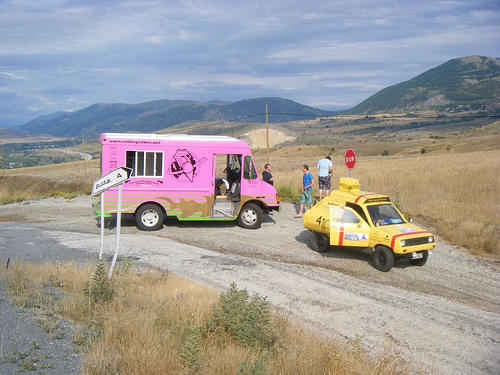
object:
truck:
[99, 132, 280, 231]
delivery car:
[302, 178, 437, 271]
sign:
[344, 149, 356, 168]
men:
[263, 155, 334, 218]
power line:
[217, 109, 420, 126]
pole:
[263, 102, 271, 169]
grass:
[355, 158, 500, 220]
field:
[0, 145, 500, 247]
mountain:
[348, 54, 500, 117]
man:
[294, 163, 316, 218]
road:
[0, 187, 500, 375]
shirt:
[302, 172, 314, 188]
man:
[317, 155, 335, 202]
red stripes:
[338, 224, 346, 245]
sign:
[90, 166, 134, 195]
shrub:
[203, 282, 280, 346]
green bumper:
[90, 202, 114, 218]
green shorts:
[300, 190, 312, 204]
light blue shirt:
[318, 158, 334, 178]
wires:
[201, 99, 498, 135]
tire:
[134, 203, 166, 231]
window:
[126, 151, 166, 176]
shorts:
[317, 175, 329, 188]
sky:
[0, 130, 500, 220]